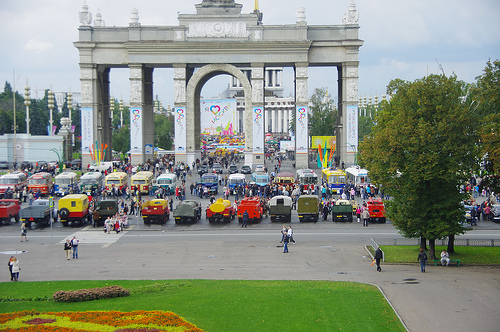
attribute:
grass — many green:
[188, 280, 391, 330]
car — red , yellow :
[58, 192, 89, 219]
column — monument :
[336, 59, 366, 171]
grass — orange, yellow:
[0, 309, 202, 330]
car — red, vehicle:
[232, 193, 266, 228]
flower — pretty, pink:
[87, 291, 93, 293]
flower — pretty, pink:
[102, 285, 104, 289]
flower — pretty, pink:
[88, 285, 95, 287]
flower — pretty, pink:
[74, 292, 81, 296]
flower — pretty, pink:
[59, 287, 66, 294]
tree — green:
[361, 71, 472, 246]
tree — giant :
[355, 59, 479, 261]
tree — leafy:
[356, 69, 486, 264]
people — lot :
[17, 159, 384, 225]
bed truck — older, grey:
[19, 197, 51, 224]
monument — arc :
[70, 2, 358, 192]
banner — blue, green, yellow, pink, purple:
[188, 75, 305, 165]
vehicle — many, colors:
[297, 192, 324, 224]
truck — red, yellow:
[201, 192, 236, 227]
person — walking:
[371, 240, 388, 270]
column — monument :
[289, 62, 321, 180]